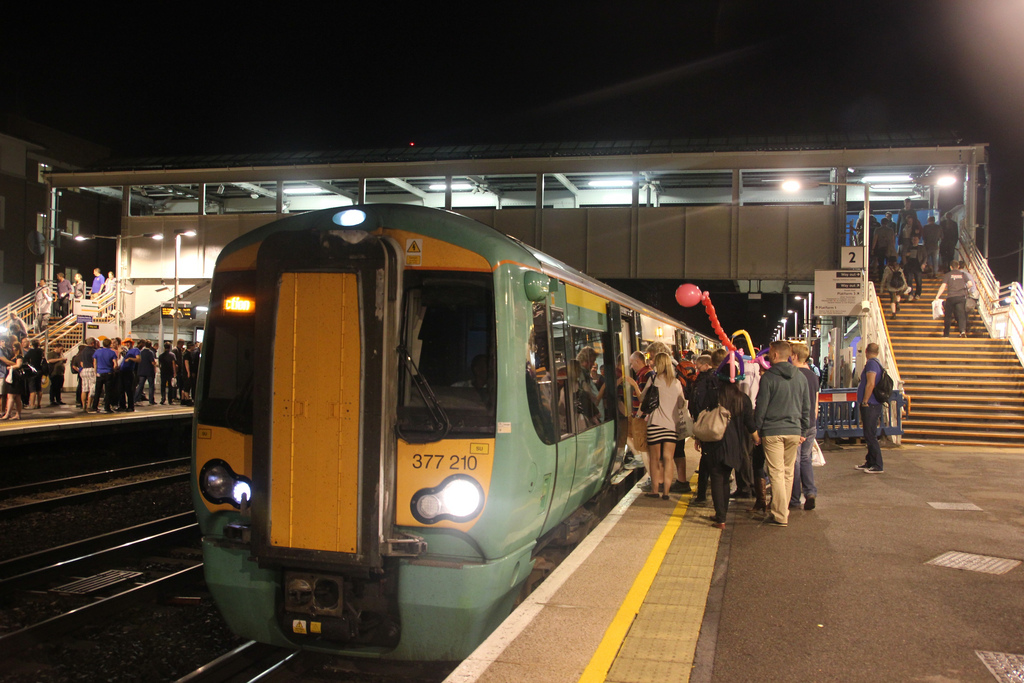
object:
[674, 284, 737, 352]
balloon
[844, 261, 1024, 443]
stairway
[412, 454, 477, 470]
number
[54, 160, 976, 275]
bridge